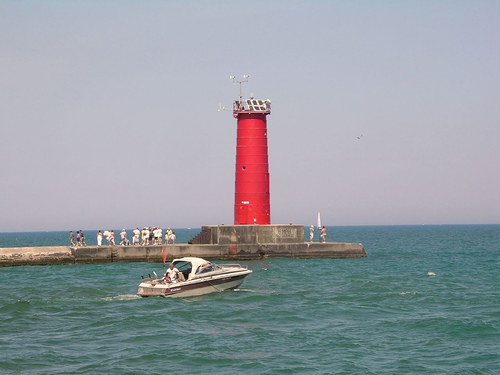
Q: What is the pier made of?
A: Concrete.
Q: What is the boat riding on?
A: Water.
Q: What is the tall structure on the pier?
A: A lighthouse.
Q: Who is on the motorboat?
A: A man.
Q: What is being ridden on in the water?
A: A boat.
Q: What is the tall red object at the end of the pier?
A: A lighthouse.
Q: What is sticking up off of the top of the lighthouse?
A: Lights.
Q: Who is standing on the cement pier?
A: Several people.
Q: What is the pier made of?
A: Cement.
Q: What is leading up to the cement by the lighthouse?
A: Stairs.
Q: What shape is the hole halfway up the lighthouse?
A: A circle.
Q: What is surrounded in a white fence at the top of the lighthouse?
A: An observation deck.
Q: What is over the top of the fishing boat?
A: A canopy.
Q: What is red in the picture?
A: A light house.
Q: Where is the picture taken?
A: The sea.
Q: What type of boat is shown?
A: A speed boat.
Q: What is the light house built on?
A: Concrete slab.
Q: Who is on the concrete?
A: Men and women.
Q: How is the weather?
A: Sunny and clear.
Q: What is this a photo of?
A: A boat and a light house.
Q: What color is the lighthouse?
A: Red.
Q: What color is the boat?
A: White and brown.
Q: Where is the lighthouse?
A: On a jetty.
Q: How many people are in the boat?
A: 2 are visible.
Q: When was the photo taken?
A: During the day time.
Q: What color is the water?
A: Greenish blue.